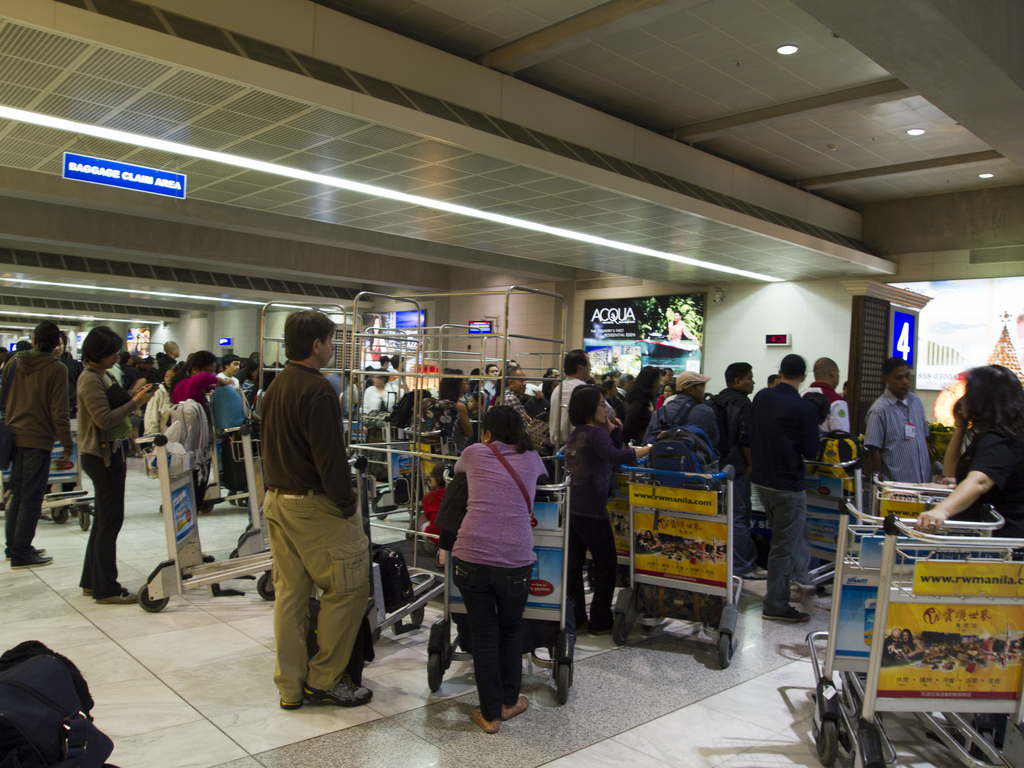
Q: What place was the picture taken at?
A: It was taken at the airport.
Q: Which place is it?
A: It is an airport.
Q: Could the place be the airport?
A: Yes, it is the airport.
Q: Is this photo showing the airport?
A: Yes, it is showing the airport.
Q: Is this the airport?
A: Yes, it is the airport.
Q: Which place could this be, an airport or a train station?
A: It is an airport.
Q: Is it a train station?
A: No, it is an airport.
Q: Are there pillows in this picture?
A: No, there are no pillows.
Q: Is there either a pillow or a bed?
A: No, there are no pillows or beds.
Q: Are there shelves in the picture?
A: No, there are no shelves.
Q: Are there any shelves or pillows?
A: No, there are no shelves or pillows.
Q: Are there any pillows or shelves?
A: No, there are no shelves or pillows.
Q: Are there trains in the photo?
A: No, there are no trains.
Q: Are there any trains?
A: No, there are no trains.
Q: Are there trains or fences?
A: No, there are no trains or fences.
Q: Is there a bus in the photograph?
A: No, there are no buses.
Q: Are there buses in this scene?
A: No, there are no buses.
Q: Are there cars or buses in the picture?
A: No, there are no buses or cars.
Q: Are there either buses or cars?
A: No, there are no buses or cars.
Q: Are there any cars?
A: No, there are no cars.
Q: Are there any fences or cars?
A: No, there are no cars or fences.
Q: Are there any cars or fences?
A: No, there are no cars or fences.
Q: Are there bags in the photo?
A: Yes, there is a bag.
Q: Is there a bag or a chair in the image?
A: Yes, there is a bag.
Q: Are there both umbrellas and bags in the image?
A: No, there is a bag but no umbrellas.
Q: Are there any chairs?
A: No, there are no chairs.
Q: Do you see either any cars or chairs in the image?
A: No, there are no chairs or cars.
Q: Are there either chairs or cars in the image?
A: No, there are no chairs or cars.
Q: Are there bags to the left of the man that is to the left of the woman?
A: Yes, there is a bag to the left of the man.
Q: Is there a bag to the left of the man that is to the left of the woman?
A: Yes, there is a bag to the left of the man.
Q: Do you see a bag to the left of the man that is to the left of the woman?
A: Yes, there is a bag to the left of the man.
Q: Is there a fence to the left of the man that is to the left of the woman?
A: No, there is a bag to the left of the man.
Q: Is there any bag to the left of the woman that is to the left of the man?
A: Yes, there is a bag to the left of the woman.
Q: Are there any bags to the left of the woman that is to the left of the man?
A: Yes, there is a bag to the left of the woman.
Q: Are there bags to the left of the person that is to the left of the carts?
A: Yes, there is a bag to the left of the woman.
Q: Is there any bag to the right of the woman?
A: No, the bag is to the left of the woman.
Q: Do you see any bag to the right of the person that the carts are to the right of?
A: No, the bag is to the left of the woman.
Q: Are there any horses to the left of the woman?
A: No, there is a bag to the left of the woman.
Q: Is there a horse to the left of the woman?
A: No, there is a bag to the left of the woman.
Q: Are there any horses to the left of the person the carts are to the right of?
A: No, there is a bag to the left of the woman.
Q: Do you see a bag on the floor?
A: Yes, there is a bag on the floor.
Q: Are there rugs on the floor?
A: No, there is a bag on the floor.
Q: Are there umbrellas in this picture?
A: No, there are no umbrellas.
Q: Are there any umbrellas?
A: No, there are no umbrellas.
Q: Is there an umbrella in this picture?
A: No, there are no umbrellas.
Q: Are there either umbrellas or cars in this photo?
A: No, there are no umbrellas or cars.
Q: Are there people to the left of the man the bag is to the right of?
A: Yes, there are people to the left of the man.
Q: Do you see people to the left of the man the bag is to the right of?
A: Yes, there are people to the left of the man.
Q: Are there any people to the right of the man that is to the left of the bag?
A: No, the people are to the left of the man.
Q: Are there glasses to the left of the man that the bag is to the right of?
A: No, there are people to the left of the man.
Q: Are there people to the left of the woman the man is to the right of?
A: Yes, there are people to the left of the woman.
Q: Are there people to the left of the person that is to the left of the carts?
A: Yes, there are people to the left of the woman.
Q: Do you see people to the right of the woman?
A: No, the people are to the left of the woman.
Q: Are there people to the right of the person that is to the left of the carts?
A: No, the people are to the left of the woman.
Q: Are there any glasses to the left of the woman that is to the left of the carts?
A: No, there are people to the left of the woman.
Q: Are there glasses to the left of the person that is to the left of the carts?
A: No, there are people to the left of the woman.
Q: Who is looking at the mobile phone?
A: The people are looking at the mobile phone.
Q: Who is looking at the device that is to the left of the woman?
A: The people are looking at the mobile phone.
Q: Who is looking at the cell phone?
A: The people are looking at the mobile phone.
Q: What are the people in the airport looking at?
A: The people are looking at the cellphone.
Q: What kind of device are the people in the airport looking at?
A: The people are looking at the cell phone.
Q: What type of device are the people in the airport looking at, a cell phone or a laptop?
A: The people are looking at a cell phone.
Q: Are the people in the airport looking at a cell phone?
A: Yes, the people are looking at a cell phone.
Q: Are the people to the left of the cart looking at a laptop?
A: No, the people are looking at a cell phone.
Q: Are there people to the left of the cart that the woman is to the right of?
A: Yes, there are people to the left of the cart.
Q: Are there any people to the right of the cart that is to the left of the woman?
A: No, the people are to the left of the cart.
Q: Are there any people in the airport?
A: Yes, there are people in the airport.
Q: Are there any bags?
A: Yes, there is a bag.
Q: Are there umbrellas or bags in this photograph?
A: Yes, there is a bag.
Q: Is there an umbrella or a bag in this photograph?
A: Yes, there is a bag.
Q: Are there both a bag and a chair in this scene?
A: No, there is a bag but no chairs.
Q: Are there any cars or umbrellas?
A: No, there are no cars or umbrellas.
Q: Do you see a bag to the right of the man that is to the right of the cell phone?
A: Yes, there is a bag to the right of the man.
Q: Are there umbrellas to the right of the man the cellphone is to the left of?
A: No, there is a bag to the right of the man.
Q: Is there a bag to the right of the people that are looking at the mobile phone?
A: Yes, there is a bag to the right of the people.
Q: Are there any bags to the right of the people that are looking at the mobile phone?
A: Yes, there is a bag to the right of the people.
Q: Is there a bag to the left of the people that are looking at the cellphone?
A: No, the bag is to the right of the people.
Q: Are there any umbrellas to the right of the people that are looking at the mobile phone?
A: No, there is a bag to the right of the people.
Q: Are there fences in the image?
A: No, there are no fences.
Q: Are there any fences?
A: No, there are no fences.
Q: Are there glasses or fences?
A: No, there are no fences or glasses.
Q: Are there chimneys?
A: No, there are no chimneys.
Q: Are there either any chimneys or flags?
A: No, there are no chimneys or flags.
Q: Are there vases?
A: No, there are no vases.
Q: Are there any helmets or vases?
A: No, there are no vases or helmets.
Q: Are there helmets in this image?
A: No, there are no helmets.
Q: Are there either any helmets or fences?
A: No, there are no helmets or fences.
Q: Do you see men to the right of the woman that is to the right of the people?
A: Yes, there is a man to the right of the woman.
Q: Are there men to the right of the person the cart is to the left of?
A: Yes, there is a man to the right of the woman.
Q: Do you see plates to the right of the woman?
A: No, there is a man to the right of the woman.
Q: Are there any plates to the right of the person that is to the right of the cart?
A: No, there is a man to the right of the woman.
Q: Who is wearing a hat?
A: The man is wearing a hat.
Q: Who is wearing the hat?
A: The man is wearing a hat.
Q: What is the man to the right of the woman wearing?
A: The man is wearing a hat.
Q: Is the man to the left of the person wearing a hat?
A: Yes, the man is wearing a hat.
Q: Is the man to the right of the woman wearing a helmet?
A: No, the man is wearing a hat.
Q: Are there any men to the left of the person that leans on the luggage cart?
A: Yes, there is a man to the left of the person.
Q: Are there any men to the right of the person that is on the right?
A: No, the man is to the left of the person.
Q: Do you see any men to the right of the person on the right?
A: No, the man is to the left of the person.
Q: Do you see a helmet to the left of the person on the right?
A: No, there is a man to the left of the person.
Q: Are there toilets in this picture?
A: No, there are no toilets.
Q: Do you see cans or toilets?
A: No, there are no toilets or cans.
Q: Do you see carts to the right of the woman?
A: Yes, there are carts to the right of the woman.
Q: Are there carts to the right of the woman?
A: Yes, there are carts to the right of the woman.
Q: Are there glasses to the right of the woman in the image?
A: No, there are carts to the right of the woman.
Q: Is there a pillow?
A: No, there are no pillows.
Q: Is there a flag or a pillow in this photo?
A: No, there are no pillows or flags.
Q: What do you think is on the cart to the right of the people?
A: The luggage is on the cart.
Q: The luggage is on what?
A: The luggage is on the cart.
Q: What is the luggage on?
A: The luggage is on the cart.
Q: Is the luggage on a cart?
A: Yes, the luggage is on a cart.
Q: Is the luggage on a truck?
A: No, the luggage is on a cart.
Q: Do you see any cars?
A: No, there are no cars.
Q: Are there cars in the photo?
A: No, there are no cars.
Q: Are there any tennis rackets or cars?
A: No, there are no cars or tennis rackets.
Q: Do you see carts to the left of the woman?
A: Yes, there is a cart to the left of the woman.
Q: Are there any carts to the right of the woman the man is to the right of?
A: No, the cart is to the left of the woman.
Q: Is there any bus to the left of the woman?
A: No, there is a cart to the left of the woman.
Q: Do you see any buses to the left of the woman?
A: No, there is a cart to the left of the woman.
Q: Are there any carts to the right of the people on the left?
A: Yes, there is a cart to the right of the people.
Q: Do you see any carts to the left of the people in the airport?
A: No, the cart is to the right of the people.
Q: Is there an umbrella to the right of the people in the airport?
A: No, there is a cart to the right of the people.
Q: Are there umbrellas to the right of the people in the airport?
A: No, there is a cart to the right of the people.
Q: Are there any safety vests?
A: No, there are no safety vests.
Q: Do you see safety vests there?
A: No, there are no safety vests.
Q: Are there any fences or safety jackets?
A: No, there are no safety jackets or fences.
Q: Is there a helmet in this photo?
A: No, there are no helmets.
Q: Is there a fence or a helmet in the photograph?
A: No, there are no helmets or fences.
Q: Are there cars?
A: No, there are no cars.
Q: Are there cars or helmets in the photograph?
A: No, there are no cars or helmets.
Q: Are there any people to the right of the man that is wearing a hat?
A: Yes, there is a person to the right of the man.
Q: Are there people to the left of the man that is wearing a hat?
A: No, the person is to the right of the man.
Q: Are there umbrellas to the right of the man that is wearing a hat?
A: No, there is a person to the right of the man.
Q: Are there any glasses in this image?
A: No, there are no glasses.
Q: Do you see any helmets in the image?
A: No, there are no helmets.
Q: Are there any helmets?
A: No, there are no helmets.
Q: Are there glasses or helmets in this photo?
A: No, there are no helmets or glasses.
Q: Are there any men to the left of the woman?
A: Yes, there is a man to the left of the woman.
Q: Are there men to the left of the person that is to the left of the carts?
A: Yes, there is a man to the left of the woman.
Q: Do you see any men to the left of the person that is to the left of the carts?
A: Yes, there is a man to the left of the woman.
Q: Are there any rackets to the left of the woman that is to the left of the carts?
A: No, there is a man to the left of the woman.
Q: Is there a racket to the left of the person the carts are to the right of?
A: No, there is a man to the left of the woman.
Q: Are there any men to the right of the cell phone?
A: Yes, there is a man to the right of the cell phone.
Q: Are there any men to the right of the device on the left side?
A: Yes, there is a man to the right of the cell phone.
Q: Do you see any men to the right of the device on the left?
A: Yes, there is a man to the right of the cell phone.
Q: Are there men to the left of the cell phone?
A: No, the man is to the right of the cell phone.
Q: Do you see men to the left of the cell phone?
A: No, the man is to the right of the cell phone.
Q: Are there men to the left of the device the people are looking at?
A: No, the man is to the right of the cell phone.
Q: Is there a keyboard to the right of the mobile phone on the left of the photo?
A: No, there is a man to the right of the cell phone.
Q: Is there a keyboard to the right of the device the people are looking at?
A: No, there is a man to the right of the cell phone.